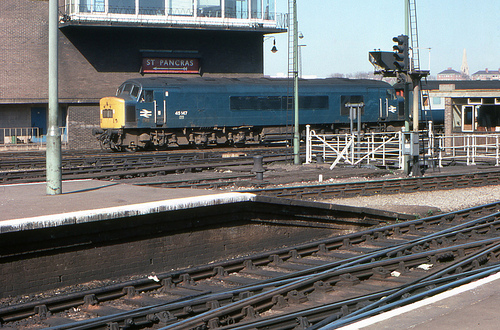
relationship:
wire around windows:
[56, 2, 291, 27] [63, 0, 278, 25]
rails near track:
[303, 125, 401, 168] [1, 205, 497, 330]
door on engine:
[129, 90, 204, 130] [102, 63, 276, 194]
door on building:
[30, 108, 48, 142] [1, 2, 288, 149]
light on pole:
[394, 33, 408, 75] [406, 47, 422, 155]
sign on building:
[140, 52, 200, 73] [6, 0, 289, 102]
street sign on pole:
[393, 84, 404, 103] [366, 30, 419, 176]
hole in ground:
[0, 191, 403, 309] [2, 135, 497, 326]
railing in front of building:
[2, 125, 44, 147] [1, 2, 288, 149]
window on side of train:
[230, 93, 243, 113] [115, 60, 431, 157]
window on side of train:
[247, 97, 260, 111] [115, 60, 431, 157]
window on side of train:
[268, 91, 280, 112] [115, 60, 431, 157]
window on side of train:
[302, 94, 316, 113] [115, 60, 431, 157]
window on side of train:
[311, 93, 331, 113] [115, 60, 431, 157]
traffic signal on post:
[387, 85, 411, 106] [407, 68, 426, 177]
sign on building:
[124, 49, 248, 91] [2, 0, 288, 176]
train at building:
[73, 64, 411, 143] [1, 2, 288, 149]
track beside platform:
[1, 205, 497, 330] [345, 267, 497, 328]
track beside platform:
[1, 205, 497, 330] [3, 180, 238, 240]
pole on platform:
[32, 5, 109, 202] [10, 160, 228, 232]